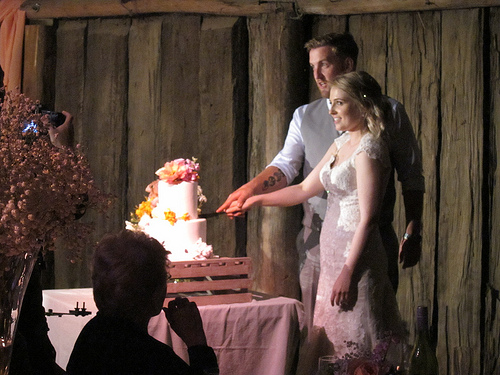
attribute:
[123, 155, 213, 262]
cake — two tier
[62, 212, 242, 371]
person — shadowed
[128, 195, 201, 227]
yellow flowers — pink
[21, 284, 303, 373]
tablecloth — white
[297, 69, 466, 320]
bride — sleeveless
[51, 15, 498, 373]
fence — wooden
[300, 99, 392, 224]
vest — gray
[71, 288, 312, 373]
table — square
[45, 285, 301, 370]
cloth — white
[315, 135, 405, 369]
dress — white